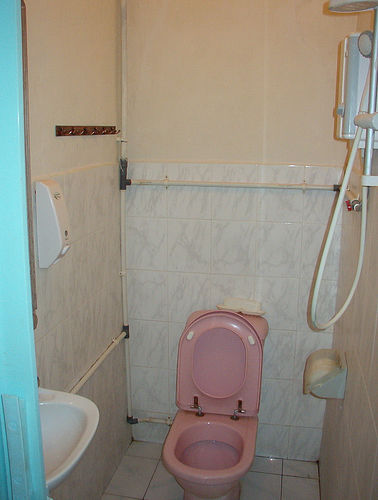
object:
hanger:
[55, 125, 121, 137]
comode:
[162, 311, 270, 499]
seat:
[161, 409, 259, 485]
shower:
[305, 0, 378, 331]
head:
[358, 31, 375, 58]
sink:
[38, 387, 101, 492]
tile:
[119, 459, 160, 499]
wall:
[146, 195, 314, 282]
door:
[2, 0, 47, 500]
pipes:
[122, 179, 348, 194]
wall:
[141, 0, 322, 150]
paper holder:
[303, 349, 347, 400]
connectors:
[120, 162, 133, 426]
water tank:
[184, 311, 269, 347]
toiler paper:
[300, 348, 347, 401]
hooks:
[68, 127, 74, 135]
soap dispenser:
[35, 180, 71, 269]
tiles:
[159, 190, 238, 255]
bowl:
[159, 414, 258, 480]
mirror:
[17, 0, 39, 331]